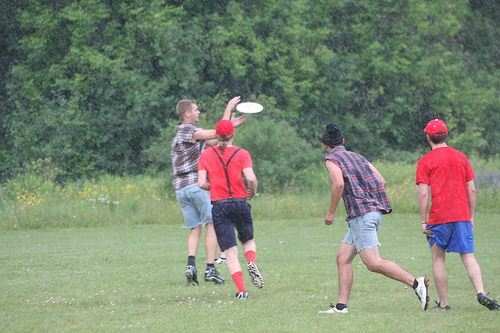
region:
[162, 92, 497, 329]
Four guys playing in a field.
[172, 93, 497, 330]
Four guys playing with a frisbee.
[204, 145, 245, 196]
Black suspenders worn by a player.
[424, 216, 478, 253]
Blue shorts worn by guy wearing red shirt.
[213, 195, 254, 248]
Black shorts worn by guy wearing red shirt.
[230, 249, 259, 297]
Red socks being worn by a man.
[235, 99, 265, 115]
White frisbee in the air.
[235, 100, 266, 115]
White frisbee about to be caught.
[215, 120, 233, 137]
Red cap worn by man wearing black shorts.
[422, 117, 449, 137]
Red cap worn by man wearing blue shorts.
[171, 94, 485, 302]
four young men playing Frisbee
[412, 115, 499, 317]
young man wearing a red cap and shirt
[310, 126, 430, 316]
young man wearing a black cap and plaid shirt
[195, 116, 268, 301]
young man wearing black suspenders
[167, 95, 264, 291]
young man about to catch the Frisbee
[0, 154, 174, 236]
wildflowers at the edge of the field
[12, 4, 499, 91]
dense trees in the background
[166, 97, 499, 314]
all the young men are wearing shorts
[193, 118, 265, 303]
young man wearing red socks and sneakers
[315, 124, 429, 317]
young man running on a grassy field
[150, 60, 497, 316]
The men are playing a game of frisbee on the field.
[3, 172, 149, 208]
Yellow flowers growing near the field.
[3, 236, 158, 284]
The grass is green.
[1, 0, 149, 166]
The trees are green.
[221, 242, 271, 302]
The man is wearing long red socks.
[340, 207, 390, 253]
The man is wearing denim shorts.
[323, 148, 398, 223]
The man is wearing a sleeveless flanel shirt.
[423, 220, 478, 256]
The man is wearing blue shorts.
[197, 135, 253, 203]
The man is wearing a red shirt.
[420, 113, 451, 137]
The man is wearing a red hat.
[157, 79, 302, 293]
boy catching white frisbee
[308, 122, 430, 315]
young man in plaid shirt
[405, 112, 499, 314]
young man in red hat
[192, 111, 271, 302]
young man in red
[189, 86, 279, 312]
frisbee player wearing black suspenders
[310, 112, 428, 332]
man wearing jean cut off shorts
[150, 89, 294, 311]
two young frisbee players in grass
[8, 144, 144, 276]
field with flowers on edge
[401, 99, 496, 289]
young man wearing red baseball cap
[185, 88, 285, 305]
man running with cleats and red socks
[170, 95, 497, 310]
teenage boys playing frisbee in the field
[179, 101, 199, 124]
head of one teenage boy catching frisbee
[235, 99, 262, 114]
frisbee being caught while flying through the air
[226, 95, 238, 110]
hand of teenage boy catching frisbee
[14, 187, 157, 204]
flowers in the tall grass behind the boys playing frisbee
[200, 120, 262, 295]
one of the teenage boys in red and black running to catch the frisbee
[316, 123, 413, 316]
second boy running to catch the frisbee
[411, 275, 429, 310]
foot of the second boy running to catch the frisbee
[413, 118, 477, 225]
top half of the third teenage boy running to catch the frisbee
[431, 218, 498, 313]
bottom half of third teenage boy running to catch a frisbee